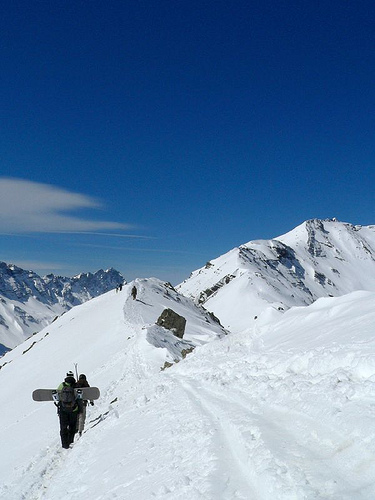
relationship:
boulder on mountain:
[154, 308, 187, 335] [85, 268, 220, 359]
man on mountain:
[56, 370, 82, 448] [6, 212, 374, 498]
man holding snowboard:
[56, 370, 82, 448] [30, 387, 101, 401]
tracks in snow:
[172, 369, 359, 498] [258, 336, 360, 402]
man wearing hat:
[56, 370, 82, 448] [63, 368, 79, 380]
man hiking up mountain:
[56, 370, 82, 448] [6, 212, 374, 498]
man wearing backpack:
[56, 370, 82, 448] [56, 382, 77, 413]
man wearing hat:
[56, 370, 82, 448] [66, 371, 72, 378]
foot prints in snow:
[15, 441, 70, 498] [2, 214, 373, 497]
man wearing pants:
[56, 370, 82, 448] [60, 407, 78, 445]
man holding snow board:
[54, 378, 81, 444] [34, 385, 53, 400]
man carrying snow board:
[56, 370, 82, 448] [30, 387, 94, 400]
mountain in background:
[0, 258, 127, 354] [1, 153, 373, 355]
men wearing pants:
[76, 374, 94, 436] [77, 400, 87, 435]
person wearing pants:
[108, 277, 127, 296] [115, 288, 119, 292]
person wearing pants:
[132, 279, 143, 305] [132, 293, 138, 299]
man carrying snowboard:
[56, 370, 82, 448] [32, 385, 100, 400]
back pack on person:
[58, 388, 80, 415] [57, 375, 82, 447]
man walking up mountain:
[56, 370, 82, 448] [6, 212, 374, 498]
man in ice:
[56, 370, 82, 448] [130, 394, 193, 487]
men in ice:
[76, 374, 94, 436] [130, 394, 193, 487]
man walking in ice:
[56, 370, 82, 448] [1, 326, 373, 498]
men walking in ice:
[76, 372, 94, 436] [1, 326, 373, 498]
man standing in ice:
[56, 370, 82, 448] [1, 275, 373, 497]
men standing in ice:
[76, 374, 94, 436] [1, 275, 373, 497]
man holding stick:
[56, 370, 82, 448] [71, 358, 80, 376]